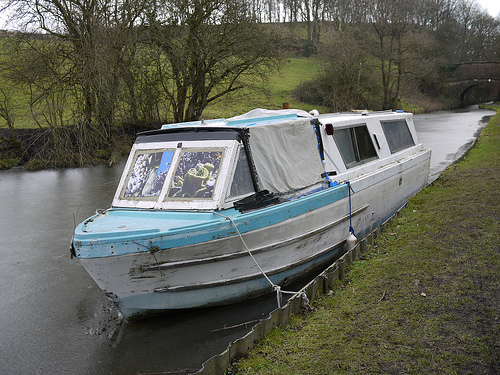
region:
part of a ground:
[395, 311, 423, 356]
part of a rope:
[248, 260, 279, 331]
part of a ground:
[416, 257, 452, 304]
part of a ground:
[398, 262, 435, 317]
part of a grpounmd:
[393, 292, 426, 337]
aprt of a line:
[163, 254, 195, 310]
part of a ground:
[406, 285, 435, 327]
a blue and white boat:
[73, 85, 443, 333]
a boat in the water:
[36, 64, 448, 349]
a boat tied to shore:
[67, 112, 499, 352]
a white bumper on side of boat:
[339, 223, 372, 277]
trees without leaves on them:
[15, 10, 261, 158]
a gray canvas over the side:
[224, 114, 336, 212]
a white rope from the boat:
[211, 203, 326, 317]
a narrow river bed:
[8, 79, 486, 372]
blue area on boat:
[63, 98, 345, 268]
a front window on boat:
[93, 134, 288, 246]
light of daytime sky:
[1, 1, 498, 32]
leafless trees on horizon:
[247, 0, 489, 23]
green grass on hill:
[1, 21, 434, 118]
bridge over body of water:
[424, 59, 497, 130]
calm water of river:
[0, 105, 495, 372]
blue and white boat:
[74, 109, 433, 321]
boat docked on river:
[71, 108, 431, 327]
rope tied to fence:
[204, 207, 311, 321]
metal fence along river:
[188, 138, 478, 372]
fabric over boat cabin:
[120, 106, 325, 219]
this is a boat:
[86, 143, 311, 216]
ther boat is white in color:
[261, 230, 316, 267]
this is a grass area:
[334, 305, 396, 352]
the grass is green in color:
[331, 288, 373, 340]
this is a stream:
[11, 210, 42, 277]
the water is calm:
[15, 216, 47, 282]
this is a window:
[339, 128, 369, 150]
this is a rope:
[235, 232, 283, 296]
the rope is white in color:
[250, 253, 267, 266]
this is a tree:
[144, 17, 218, 64]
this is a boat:
[63, 106, 412, 291]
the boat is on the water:
[68, 109, 380, 306]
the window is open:
[339, 121, 373, 165]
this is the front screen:
[121, 141, 224, 198]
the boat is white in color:
[380, 153, 417, 195]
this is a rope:
[255, 273, 296, 299]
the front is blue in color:
[80, 210, 181, 242]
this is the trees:
[141, 15, 253, 77]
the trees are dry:
[67, 15, 222, 93]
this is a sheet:
[259, 110, 312, 191]